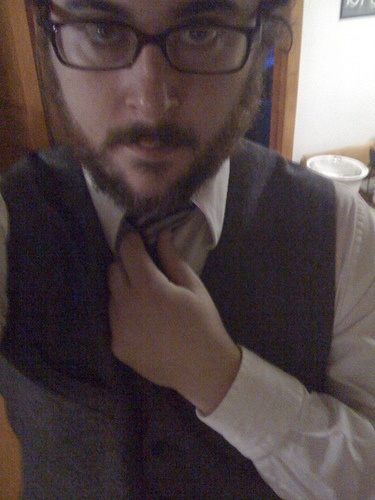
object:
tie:
[122, 199, 194, 269]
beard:
[41, 46, 264, 214]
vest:
[6, 137, 354, 499]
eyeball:
[81, 19, 127, 46]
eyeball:
[180, 23, 219, 45]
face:
[49, 2, 254, 195]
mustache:
[105, 125, 196, 170]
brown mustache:
[107, 119, 201, 150]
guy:
[0, 1, 371, 497]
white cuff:
[194, 343, 309, 461]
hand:
[108, 229, 219, 385]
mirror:
[340, 0, 372, 20]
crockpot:
[306, 152, 368, 194]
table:
[302, 146, 374, 208]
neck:
[97, 178, 214, 244]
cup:
[306, 153, 370, 192]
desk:
[298, 141, 373, 209]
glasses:
[51, 11, 259, 76]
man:
[21, 8, 357, 498]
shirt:
[0, 150, 374, 498]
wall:
[291, 0, 373, 165]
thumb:
[153, 222, 204, 292]